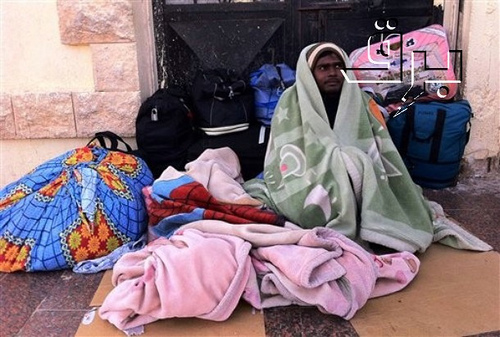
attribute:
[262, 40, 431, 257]
man — sitting, dark skinned, wrapped in blanket, wrapped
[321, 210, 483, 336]
cardboard — flat, on the right side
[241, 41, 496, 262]
blanket — green, wadded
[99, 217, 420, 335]
blanket — pink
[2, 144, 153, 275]
blanket — blue red, yellow, blue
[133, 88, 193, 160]
bag — black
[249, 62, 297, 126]
bag — blue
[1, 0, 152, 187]
wall — brick, mortar, pink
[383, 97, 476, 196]
bag — large, blue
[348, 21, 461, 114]
suitcase — pink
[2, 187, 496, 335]
sidewalk — tiled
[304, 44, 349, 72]
cap — knit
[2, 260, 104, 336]
floor — tile, red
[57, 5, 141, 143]
stones — at doorframe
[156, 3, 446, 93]
door — black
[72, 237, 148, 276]
clothes — tied together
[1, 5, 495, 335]
picture — day time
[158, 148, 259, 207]
sheets — pink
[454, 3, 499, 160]
wall — beige